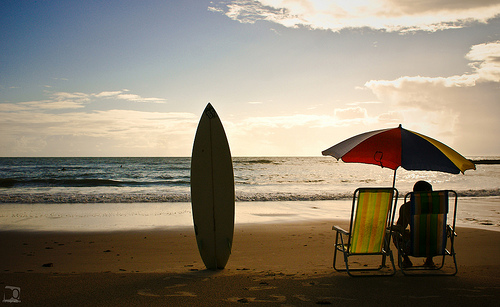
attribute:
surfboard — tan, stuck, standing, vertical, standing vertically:
[192, 98, 235, 274]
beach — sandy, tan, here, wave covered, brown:
[9, 196, 499, 298]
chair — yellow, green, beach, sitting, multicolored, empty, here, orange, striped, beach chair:
[330, 185, 401, 278]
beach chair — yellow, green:
[333, 184, 401, 281]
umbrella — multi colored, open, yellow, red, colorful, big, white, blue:
[319, 122, 482, 271]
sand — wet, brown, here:
[6, 193, 499, 301]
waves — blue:
[6, 158, 499, 206]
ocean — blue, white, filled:
[1, 158, 496, 202]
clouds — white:
[2, 1, 500, 148]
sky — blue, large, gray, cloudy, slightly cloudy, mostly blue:
[0, 4, 499, 154]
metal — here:
[333, 184, 402, 276]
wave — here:
[7, 179, 500, 200]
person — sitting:
[393, 177, 453, 268]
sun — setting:
[236, 115, 500, 156]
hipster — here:
[393, 177, 453, 270]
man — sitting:
[393, 181, 459, 265]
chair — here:
[395, 187, 458, 277]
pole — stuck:
[382, 169, 399, 267]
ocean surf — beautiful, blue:
[0, 154, 500, 202]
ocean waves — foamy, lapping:
[5, 165, 498, 202]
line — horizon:
[3, 7, 499, 159]